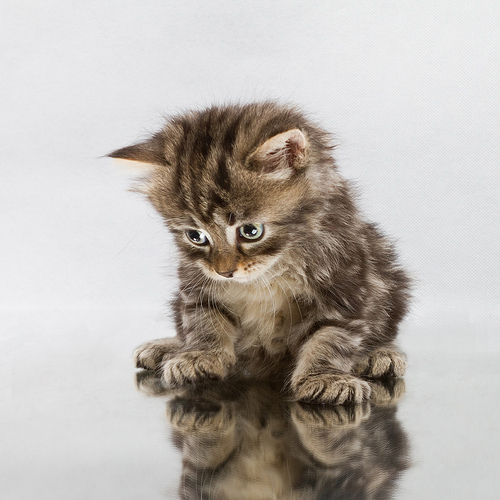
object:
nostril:
[227, 272, 234, 278]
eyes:
[182, 226, 210, 248]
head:
[104, 100, 352, 284]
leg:
[133, 331, 190, 371]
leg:
[353, 338, 406, 378]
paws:
[167, 363, 200, 391]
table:
[1, 344, 493, 494]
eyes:
[234, 218, 269, 240]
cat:
[99, 102, 415, 405]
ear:
[242, 126, 322, 168]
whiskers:
[264, 288, 315, 335]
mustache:
[212, 272, 242, 297]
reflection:
[148, 387, 420, 499]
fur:
[160, 115, 233, 162]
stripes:
[166, 111, 242, 193]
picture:
[8, 4, 495, 498]